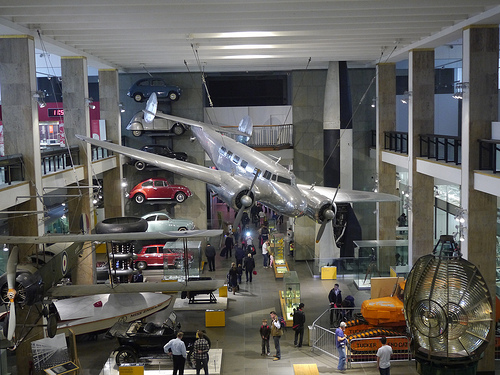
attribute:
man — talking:
[162, 333, 186, 370]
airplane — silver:
[76, 91, 421, 239]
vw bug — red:
[125, 76, 179, 103]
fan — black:
[421, 252, 468, 342]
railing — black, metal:
[418, 133, 465, 162]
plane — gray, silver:
[67, 87, 402, 247]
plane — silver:
[97, 98, 408, 243]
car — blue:
[121, 77, 181, 106]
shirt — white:
[162, 338, 187, 358]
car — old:
[107, 319, 207, 367]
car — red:
[125, 184, 200, 204]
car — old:
[113, 321, 202, 357]